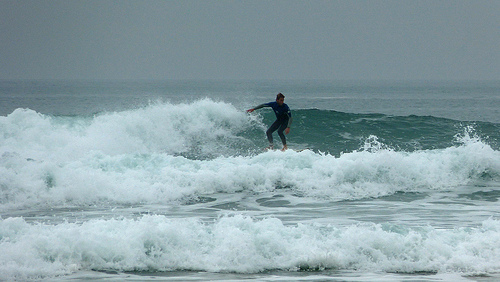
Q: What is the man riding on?
A: Surfboard.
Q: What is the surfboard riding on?
A: Wave.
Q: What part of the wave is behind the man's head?
A: Crest.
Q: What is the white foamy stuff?
A: Water.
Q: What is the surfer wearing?
A: Wetsuit.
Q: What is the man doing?
A: Surfing.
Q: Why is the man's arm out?
A: Balance.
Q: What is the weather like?
A: Overcast.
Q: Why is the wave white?
A: It is crashing.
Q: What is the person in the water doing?
A: The man is surfing.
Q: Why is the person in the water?
A: The man is surfing.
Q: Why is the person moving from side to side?
A: The man is surfing.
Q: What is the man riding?
A: The waves are visible.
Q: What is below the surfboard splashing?
A: The waves are visible.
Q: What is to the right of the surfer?
A: The waves are visible.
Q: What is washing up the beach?
A: The waves are visible.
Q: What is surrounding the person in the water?
A: The waves are visible.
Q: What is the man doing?
A: Surfing.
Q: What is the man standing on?
A: Surfboard.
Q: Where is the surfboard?
A: Ocean.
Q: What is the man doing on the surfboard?
A: Riding a wave.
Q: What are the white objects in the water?
A: Waves.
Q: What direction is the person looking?
A: Right.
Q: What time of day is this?
A: Daylight hours.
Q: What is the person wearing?
A: Wetsuit.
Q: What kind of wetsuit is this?
A: Black wetsuit.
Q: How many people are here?
A: 1.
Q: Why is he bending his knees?
A: T balance.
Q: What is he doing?
A: Surfing.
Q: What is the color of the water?
A: Green.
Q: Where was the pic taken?
A: In the ocean.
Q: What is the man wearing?
A: Swimsuit.